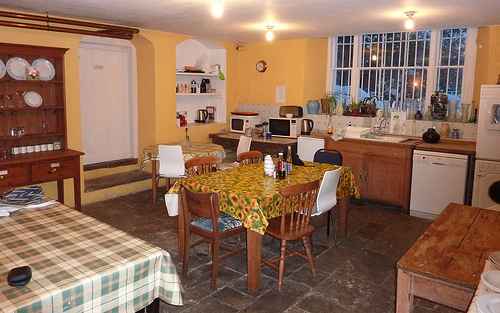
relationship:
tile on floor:
[340, 254, 391, 289] [69, 182, 469, 312]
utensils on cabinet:
[0, 55, 57, 110] [0, 41, 85, 212]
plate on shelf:
[31, 58, 57, 84] [0, 42, 85, 210]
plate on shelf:
[6, 56, 31, 80] [0, 42, 85, 210]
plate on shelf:
[0, 57, 10, 78] [0, 42, 85, 210]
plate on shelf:
[22, 91, 42, 107] [0, 42, 85, 210]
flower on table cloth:
[225, 193, 242, 210] [203, 161, 260, 215]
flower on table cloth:
[249, 209, 261, 222] [203, 161, 260, 215]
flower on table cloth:
[234, 210, 245, 224] [203, 161, 260, 215]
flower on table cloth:
[198, 185, 210, 191] [203, 161, 260, 215]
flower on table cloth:
[185, 178, 204, 192] [203, 161, 260, 215]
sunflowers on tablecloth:
[167, 155, 363, 233] [161, 156, 365, 237]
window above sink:
[324, 24, 479, 116] [348, 119, 413, 144]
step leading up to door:
[83, 166, 155, 204] [76, 42, 138, 162]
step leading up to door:
[81, 152, 138, 182] [76, 42, 138, 162]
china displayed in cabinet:
[5, 55, 56, 80] [0, 43, 87, 212]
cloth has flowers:
[163, 158, 362, 233] [228, 169, 269, 214]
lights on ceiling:
[249, 17, 287, 44] [191, 0, 451, 42]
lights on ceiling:
[201, 0, 441, 44] [191, 0, 451, 42]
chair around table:
[177, 182, 245, 290] [178, 154, 353, 294]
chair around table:
[184, 154, 242, 252] [178, 154, 353, 294]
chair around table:
[235, 150, 265, 165] [178, 154, 353, 294]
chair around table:
[311, 147, 342, 237] [178, 154, 353, 294]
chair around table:
[260, 179, 320, 294] [178, 154, 353, 294]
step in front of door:
[81, 158, 137, 182] [78, 40, 135, 166]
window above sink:
[332, 24, 467, 116] [356, 132, 416, 142]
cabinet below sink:
[326, 132, 413, 210] [347, 123, 411, 150]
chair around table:
[237, 151, 264, 170] [193, 157, 346, 198]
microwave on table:
[267, 116, 300, 138] [211, 128, 296, 156]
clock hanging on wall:
[253, 57, 267, 73] [237, 38, 304, 109]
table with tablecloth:
[165, 174, 330, 264] [196, 146, 291, 208]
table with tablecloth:
[137, 294, 163, 311] [1, 163, 190, 303]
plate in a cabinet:
[6, 56, 31, 81] [0, 43, 87, 212]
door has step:
[78, 34, 138, 167] [77, 156, 154, 203]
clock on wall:
[256, 60, 269, 73] [226, 25, 498, 124]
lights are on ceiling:
[201, 0, 441, 44] [449, 9, 473, 21]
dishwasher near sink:
[408, 149, 471, 221] [347, 125, 409, 144]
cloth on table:
[163, 158, 362, 233] [146, 124, 402, 269]